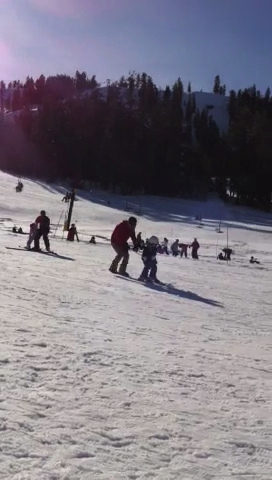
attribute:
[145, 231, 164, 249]
helmet — white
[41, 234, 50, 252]
leg — apart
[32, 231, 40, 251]
leg — apart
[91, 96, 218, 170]
trees — tall, evergreen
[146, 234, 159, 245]
hat — white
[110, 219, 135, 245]
jacket — red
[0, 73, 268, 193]
hillside — snowy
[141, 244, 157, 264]
coat — dark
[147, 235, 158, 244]
hat — white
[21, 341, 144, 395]
snow — blemished, marked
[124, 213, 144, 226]
hat — black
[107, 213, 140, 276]
adult — skiing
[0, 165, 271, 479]
hill — snow covered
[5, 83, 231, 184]
rock formation — snow covered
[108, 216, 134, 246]
parka — red